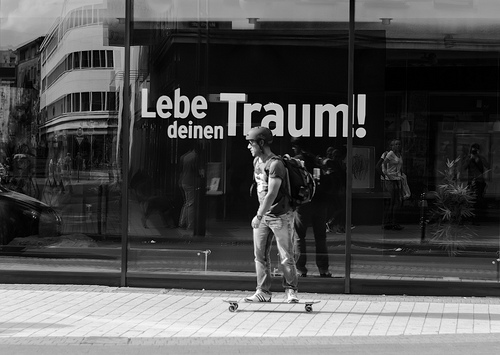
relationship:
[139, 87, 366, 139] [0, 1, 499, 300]
words are on building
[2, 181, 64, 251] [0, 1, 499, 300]
car reflected on building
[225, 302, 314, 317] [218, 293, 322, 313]
wheels attached to board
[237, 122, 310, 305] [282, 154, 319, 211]
man wears backpack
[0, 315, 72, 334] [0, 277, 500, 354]
shadow is on floor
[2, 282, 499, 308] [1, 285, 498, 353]
edge on road